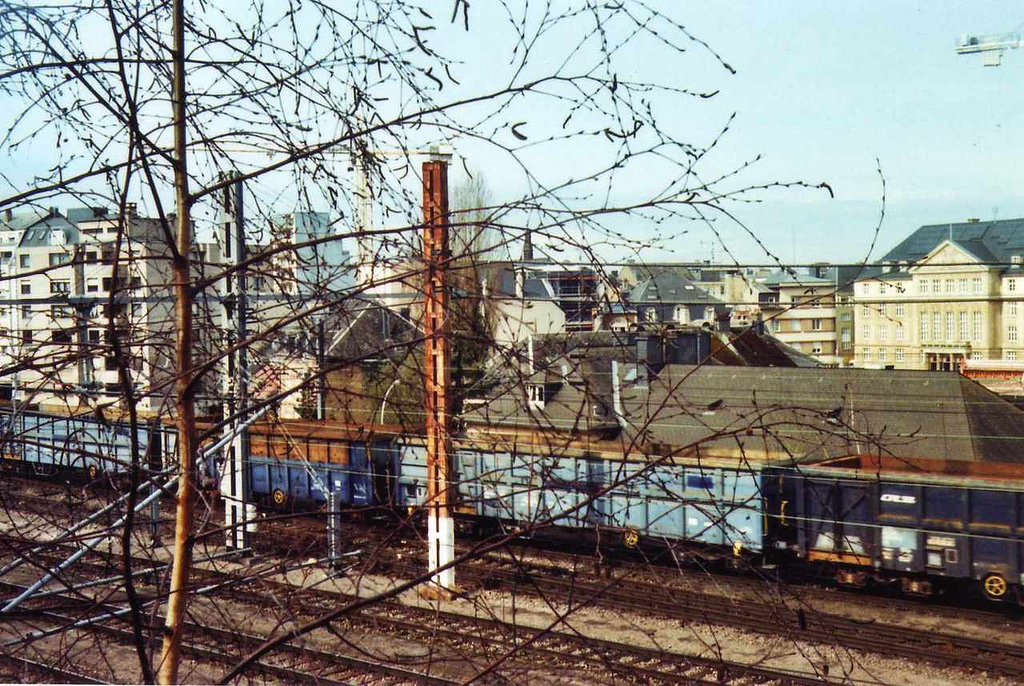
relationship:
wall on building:
[855, 279, 1023, 369] [854, 218, 1022, 368]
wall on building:
[3, 243, 147, 412] [2, 204, 224, 419]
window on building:
[49, 252, 74, 266] [2, 204, 224, 419]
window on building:
[916, 278, 930, 296] [854, 218, 1022, 368]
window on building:
[893, 323, 906, 342] [854, 218, 1022, 368]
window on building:
[48, 276, 75, 296] [2, 204, 224, 419]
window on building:
[19, 253, 33, 271] [2, 204, 224, 419]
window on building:
[20, 302, 37, 323] [2, 204, 224, 419]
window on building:
[862, 283, 872, 303] [854, 218, 1022, 368]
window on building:
[21, 326, 35, 350] [2, 204, 224, 419]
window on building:
[860, 324, 874, 338] [854, 218, 1022, 368]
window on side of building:
[810, 318, 824, 332] [758, 272, 838, 361]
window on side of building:
[789, 295, 806, 310] [758, 272, 838, 361]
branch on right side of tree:
[195, 303, 600, 445] [3, 2, 821, 685]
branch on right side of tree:
[187, 3, 741, 205] [3, 2, 821, 685]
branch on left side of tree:
[1, 6, 183, 165] [3, 2, 821, 685]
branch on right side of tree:
[193, 319, 670, 442] [3, 2, 821, 685]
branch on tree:
[214, 393, 926, 684] [3, 2, 821, 685]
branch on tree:
[189, 453, 709, 552] [3, 2, 821, 685]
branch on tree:
[92, 1, 190, 272] [3, 2, 821, 685]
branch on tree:
[109, 2, 164, 684] [3, 2, 821, 685]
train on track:
[1, 395, 1019, 604] [7, 459, 1021, 676]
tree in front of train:
[3, 2, 821, 685] [1, 395, 1019, 604]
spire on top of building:
[522, 213, 537, 261] [488, 259, 614, 333]